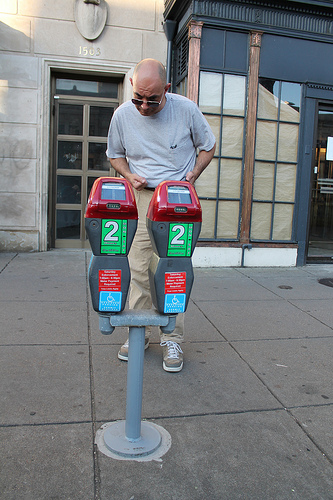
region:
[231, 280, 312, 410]
this is a pavement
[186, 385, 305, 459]
the pavement is big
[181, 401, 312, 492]
the pavement is made of stone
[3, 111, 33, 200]
this is the wall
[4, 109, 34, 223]
the wall is made of stone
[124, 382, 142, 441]
this is a pole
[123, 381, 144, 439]
the pole is blue in color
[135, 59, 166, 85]
the hair is bald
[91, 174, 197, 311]
this is a parking toll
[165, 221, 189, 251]
this is a digit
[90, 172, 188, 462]
two parking meters on a metal post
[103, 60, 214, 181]
a man wearing sunglasses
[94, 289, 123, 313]
a blue handicapped sticker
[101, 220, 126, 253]
number two on a green sticker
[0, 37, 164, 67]
number 1503 on a building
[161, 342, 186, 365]
white shoeslaces that are tied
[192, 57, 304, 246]
brown paper over the inside of a window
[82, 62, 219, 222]
a man staring at a parking meter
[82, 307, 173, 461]
a metal post attached to a circular mount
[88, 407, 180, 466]
a painted mount on the ground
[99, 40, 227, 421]
This is a man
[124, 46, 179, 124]
Head of a man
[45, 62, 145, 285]
This is a door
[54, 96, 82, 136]
Pane of a door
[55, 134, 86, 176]
Pane of a door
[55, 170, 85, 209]
Pane of a door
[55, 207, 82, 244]
Pane of a door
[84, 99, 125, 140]
Pane of a door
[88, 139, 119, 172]
Pane of a door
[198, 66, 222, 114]
Pane of a door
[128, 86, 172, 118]
dark glasses on man's nose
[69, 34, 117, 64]
number 1503 on building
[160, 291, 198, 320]
light blue handicapped label on meter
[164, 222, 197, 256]
white number 2 on green background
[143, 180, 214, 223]
red upper portion of parking meter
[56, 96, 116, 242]
door with eight panes of glass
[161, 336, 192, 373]
man's left tan shoe with white laces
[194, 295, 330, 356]
grey cement square on sidewalk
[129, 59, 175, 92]
balding head on man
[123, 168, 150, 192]
man's right hand balled into fist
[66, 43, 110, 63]
address on a building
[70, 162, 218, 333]
parking meters on a sidewalk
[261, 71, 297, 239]
windows on a building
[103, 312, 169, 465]
pole of a parking meter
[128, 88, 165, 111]
sunglasses on a man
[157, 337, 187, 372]
left sneaker on a man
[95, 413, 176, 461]
base of a parking meter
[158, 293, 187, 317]
handicap sign on a parking meter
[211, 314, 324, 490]
paved tiles of a sidewalk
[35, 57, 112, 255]
entrance to a building